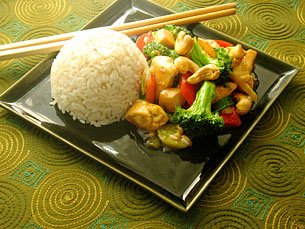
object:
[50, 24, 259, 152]
meal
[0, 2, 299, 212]
plate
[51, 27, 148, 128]
rice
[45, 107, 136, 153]
shadow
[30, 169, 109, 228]
shapes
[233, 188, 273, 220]
lines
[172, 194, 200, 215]
corner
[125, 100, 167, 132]
chicken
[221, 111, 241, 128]
pepper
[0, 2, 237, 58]
chop stick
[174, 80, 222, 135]
broccili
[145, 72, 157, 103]
carrot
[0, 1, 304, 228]
cloth